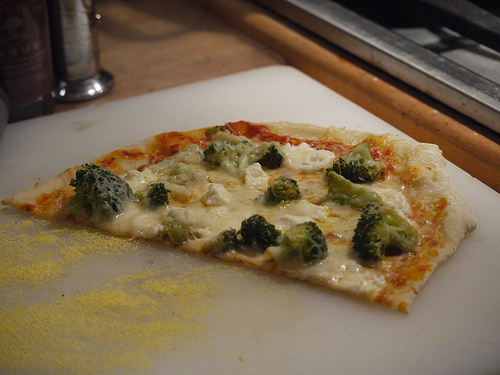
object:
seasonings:
[3, 212, 221, 374]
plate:
[2, 64, 499, 374]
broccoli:
[351, 200, 419, 263]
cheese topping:
[0, 120, 478, 314]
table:
[5, 2, 499, 367]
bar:
[273, 1, 499, 131]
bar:
[204, 0, 500, 162]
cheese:
[276, 142, 334, 172]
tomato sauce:
[161, 111, 386, 160]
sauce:
[102, 123, 397, 187]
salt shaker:
[47, 0, 113, 105]